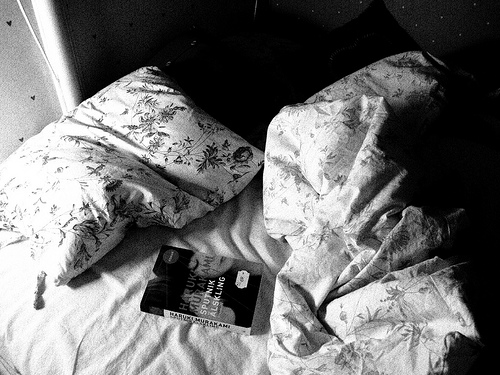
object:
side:
[142, 244, 265, 327]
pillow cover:
[300, 49, 451, 112]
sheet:
[261, 94, 481, 375]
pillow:
[304, 51, 448, 141]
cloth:
[261, 94, 481, 375]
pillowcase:
[2, 55, 262, 274]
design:
[125, 93, 184, 156]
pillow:
[0, 65, 265, 287]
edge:
[140, 304, 252, 336]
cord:
[16, 0, 68, 113]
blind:
[0, 0, 63, 164]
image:
[141, 244, 263, 328]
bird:
[140, 244, 265, 335]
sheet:
[0, 185, 290, 374]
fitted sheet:
[0, 186, 293, 375]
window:
[56, 0, 500, 151]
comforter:
[262, 94, 479, 375]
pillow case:
[0, 66, 265, 287]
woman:
[189, 251, 264, 278]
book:
[140, 244, 265, 336]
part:
[177, 248, 203, 324]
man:
[180, 288, 236, 324]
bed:
[0, 0, 499, 375]